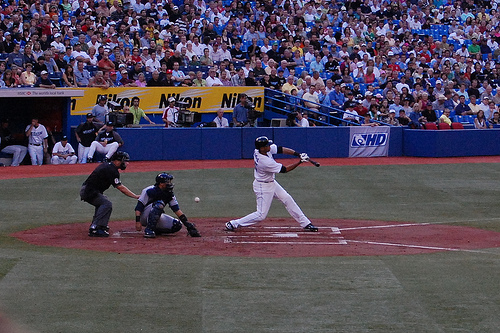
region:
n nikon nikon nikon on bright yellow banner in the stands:
[46, 84, 265, 116]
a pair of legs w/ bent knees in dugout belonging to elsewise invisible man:
[0, 140, 30, 168]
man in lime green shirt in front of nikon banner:
[120, 93, 158, 125]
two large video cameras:
[98, 100, 203, 129]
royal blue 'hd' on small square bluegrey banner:
[351, 127, 391, 151]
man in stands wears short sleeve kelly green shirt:
[465, 36, 484, 59]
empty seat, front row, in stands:
[455, 112, 472, 127]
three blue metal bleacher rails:
[258, 85, 401, 128]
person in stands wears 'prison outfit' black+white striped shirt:
[174, 18, 192, 33]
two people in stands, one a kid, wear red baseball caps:
[106, 63, 180, 85]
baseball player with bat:
[219, 130, 336, 237]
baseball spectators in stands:
[291, 28, 406, 78]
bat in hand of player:
[296, 148, 326, 175]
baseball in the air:
[188, 188, 214, 208]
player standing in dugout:
[23, 112, 50, 173]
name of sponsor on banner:
[162, 84, 258, 117]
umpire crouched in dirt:
[73, 147, 145, 241]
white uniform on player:
[244, 163, 310, 233]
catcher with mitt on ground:
[146, 170, 205, 242]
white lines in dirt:
[301, 230, 361, 252]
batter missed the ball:
[256, 136, 333, 246]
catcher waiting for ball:
[145, 162, 201, 252]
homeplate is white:
[265, 223, 329, 255]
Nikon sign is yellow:
[92, 82, 275, 121]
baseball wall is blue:
[136, 126, 303, 161]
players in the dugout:
[13, 112, 100, 169]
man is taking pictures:
[169, 94, 206, 132]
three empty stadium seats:
[428, 120, 458, 140]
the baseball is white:
[191, 195, 205, 208]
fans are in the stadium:
[23, 24, 184, 73]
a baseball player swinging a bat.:
[217, 130, 323, 244]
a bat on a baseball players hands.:
[293, 140, 328, 175]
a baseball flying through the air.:
[188, 188, 205, 203]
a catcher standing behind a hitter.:
[132, 171, 199, 249]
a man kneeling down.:
[71, 148, 146, 243]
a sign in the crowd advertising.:
[342, 111, 398, 170]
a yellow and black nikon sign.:
[53, 70, 272, 122]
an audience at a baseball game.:
[0, 5, 497, 167]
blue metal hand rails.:
[249, 85, 405, 127]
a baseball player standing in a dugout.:
[20, 113, 57, 164]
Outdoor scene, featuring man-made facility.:
[6, 2, 498, 325]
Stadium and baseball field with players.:
[0, 3, 496, 330]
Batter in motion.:
[235, 124, 327, 236]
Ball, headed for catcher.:
[188, 187, 205, 211]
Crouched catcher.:
[133, 170, 200, 249]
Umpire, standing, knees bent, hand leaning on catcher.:
[69, 147, 141, 252]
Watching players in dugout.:
[6, 112, 133, 163]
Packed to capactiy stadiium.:
[7, 10, 494, 127]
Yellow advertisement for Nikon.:
[71, 82, 266, 117]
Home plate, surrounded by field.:
[192, 159, 498, 331]